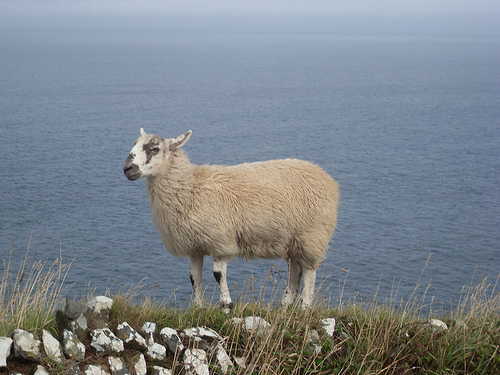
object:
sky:
[3, 2, 498, 30]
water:
[3, 34, 500, 306]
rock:
[158, 326, 182, 354]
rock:
[180, 325, 218, 349]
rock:
[89, 327, 124, 355]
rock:
[41, 328, 58, 359]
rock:
[73, 294, 115, 333]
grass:
[4, 256, 499, 374]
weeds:
[419, 337, 475, 372]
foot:
[216, 300, 234, 316]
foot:
[298, 303, 314, 317]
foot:
[277, 303, 288, 314]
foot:
[190, 301, 207, 314]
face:
[122, 133, 166, 181]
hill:
[1, 293, 498, 374]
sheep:
[121, 125, 338, 319]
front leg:
[188, 248, 203, 312]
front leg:
[210, 255, 229, 316]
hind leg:
[296, 257, 317, 311]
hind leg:
[282, 255, 299, 308]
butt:
[302, 158, 339, 222]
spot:
[188, 271, 198, 284]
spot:
[212, 269, 224, 282]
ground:
[4, 293, 499, 373]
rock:
[420, 316, 449, 335]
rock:
[306, 329, 323, 354]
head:
[120, 126, 192, 183]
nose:
[119, 163, 131, 174]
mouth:
[120, 172, 136, 179]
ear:
[170, 128, 193, 151]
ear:
[136, 126, 147, 137]